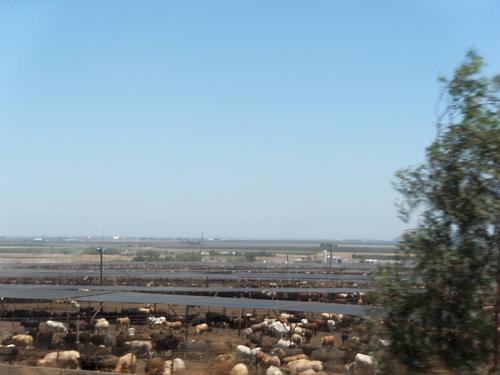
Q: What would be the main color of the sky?
A: Blue.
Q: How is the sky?
A: Clear.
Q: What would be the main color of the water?
A: Blue.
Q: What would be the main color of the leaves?
A: Green.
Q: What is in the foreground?
A: Trees.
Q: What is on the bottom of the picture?
A: Cows.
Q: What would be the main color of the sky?
A: Blue and white.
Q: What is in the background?
A: Buildings.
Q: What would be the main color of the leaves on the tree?
A: Green.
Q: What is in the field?
A: Cows.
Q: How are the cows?
A: Grouped.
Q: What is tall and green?
A: Tree.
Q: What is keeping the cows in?
A: Fence.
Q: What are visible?
A: The animals are.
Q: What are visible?
A: The brown live stocks.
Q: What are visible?
A: The water next to the fence and animals.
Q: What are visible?
A: The grass the live stocks eats.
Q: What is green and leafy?
A: The tree is.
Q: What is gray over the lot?
A: The roof is.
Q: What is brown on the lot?
A: The dirt is brown.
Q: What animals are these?
A: Cows.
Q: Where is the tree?
A: On the right.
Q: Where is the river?
A: Behind the cows.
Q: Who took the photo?
A: Tourist.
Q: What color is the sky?
A: Blue.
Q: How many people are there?
A: Zero.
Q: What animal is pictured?
A: Cows.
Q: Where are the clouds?
A: Atmosphere.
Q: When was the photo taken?
A: Afternoon.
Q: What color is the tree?
A: Green.